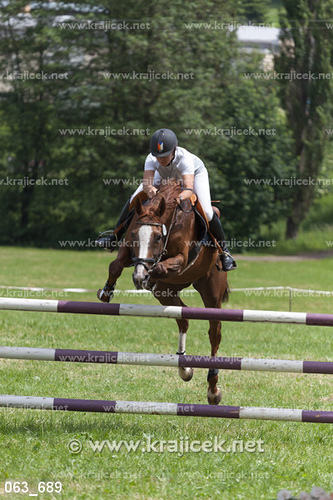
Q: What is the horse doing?
A: Jumping.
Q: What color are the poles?
A: White and brown.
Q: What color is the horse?
A: Brown and white.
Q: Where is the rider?
A: On horseback.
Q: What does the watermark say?
A: Www.kraiicek.net.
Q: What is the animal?
A: Horse.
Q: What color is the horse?
A: Brown.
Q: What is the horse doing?
A: Jumping an obstacle.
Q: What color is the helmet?
A: Black.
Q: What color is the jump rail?
A: Black and white.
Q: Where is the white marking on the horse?
A: On its face.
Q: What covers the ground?
A: Grass.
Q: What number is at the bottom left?
A: 063_689.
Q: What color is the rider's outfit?
A: White.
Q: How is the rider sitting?
A: Leaning forward.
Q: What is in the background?
A: Trees.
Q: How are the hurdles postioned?
A: On top of each other.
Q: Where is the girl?
A: On the horse.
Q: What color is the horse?
A: Brown.